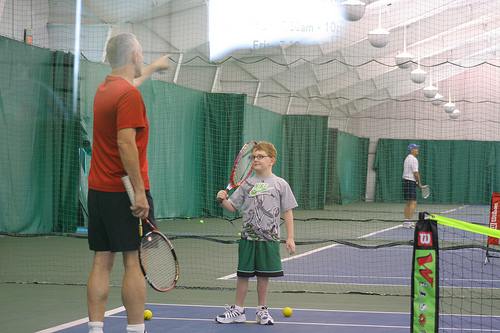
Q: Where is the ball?
A: Ground.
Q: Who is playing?
A: Child.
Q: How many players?
A: Three.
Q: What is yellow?
A: Ball.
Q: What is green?
A: Shorts.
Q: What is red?
A: Shirt.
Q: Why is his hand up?
A: Pointing.